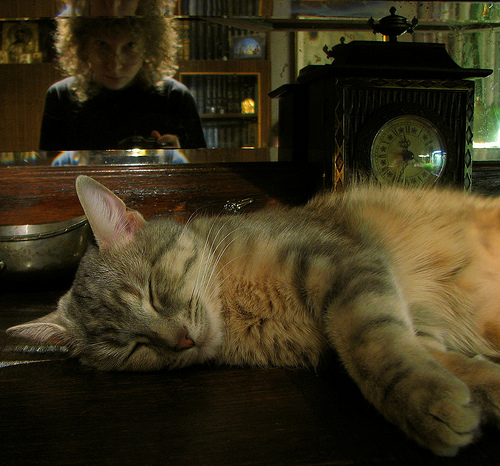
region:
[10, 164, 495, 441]
cat sleeping on the counter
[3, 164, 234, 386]
head of a sleeping cat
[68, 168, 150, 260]
fuzzy pink ear of cat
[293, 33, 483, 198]
wood encased clock with roman numerals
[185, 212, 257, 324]
white whiskers on a cat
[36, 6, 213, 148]
curly haired lady with glasses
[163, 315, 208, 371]
triangular pink nose of cat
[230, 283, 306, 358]
brown bib on a cat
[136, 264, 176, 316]
slitted eye of a cat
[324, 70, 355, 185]
decorative trim around a clock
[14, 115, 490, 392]
a cat laying on table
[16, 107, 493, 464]
a cat inside the house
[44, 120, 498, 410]
a cat laying inside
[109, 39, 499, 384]
a cat laying in front of a clock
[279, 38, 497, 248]
a clock behind the cat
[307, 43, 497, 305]
a clock behind a cat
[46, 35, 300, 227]
a women looking in the mirror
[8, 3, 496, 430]
a women and a cat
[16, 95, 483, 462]
a sleeping cat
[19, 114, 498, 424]
a sleeping cat inside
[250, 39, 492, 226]
clock on a brown box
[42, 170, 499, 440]
cat sleeping in front of mirror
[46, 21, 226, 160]
woman's reflection in mirror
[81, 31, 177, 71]
woman wearing eye glasses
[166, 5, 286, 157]
large brown book shelf in background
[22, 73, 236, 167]
woman wearing black shirt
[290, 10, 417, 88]
poster on wall in reflection in mirror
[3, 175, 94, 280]
silver bowl under brown shelf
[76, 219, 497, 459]
grey and brown cat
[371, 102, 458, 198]
white clock face with black numbers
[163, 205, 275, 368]
LONG WHITE CAT WHISKERS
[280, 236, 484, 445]
STRIPED CAT PAWS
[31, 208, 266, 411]
CAT'S FACE WHILE SLEEPING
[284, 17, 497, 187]
CLOCK SITTING IN BACKGROUND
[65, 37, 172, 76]
WOMAN WITH GLASSES ON HER NOSE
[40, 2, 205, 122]
WOMAN WITH VERY CURLY HAIR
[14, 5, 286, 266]
WOMAN TAKING PICTURE OF A CAT LAYING NEXT TO A MIRROR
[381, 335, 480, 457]
A CAT PAW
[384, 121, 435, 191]
CLOCK ARMS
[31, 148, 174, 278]
A CAT EAR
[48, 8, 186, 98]
a woman with wild curly hair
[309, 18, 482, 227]
a clock on a shelf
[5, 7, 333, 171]
a mirror on a dresser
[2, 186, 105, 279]
a silver bowl on a dresser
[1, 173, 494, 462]
a brown wooden dresser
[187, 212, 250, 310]
white whiskers on a cat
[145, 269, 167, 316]
a closed cat eye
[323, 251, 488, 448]
the front leg of a cat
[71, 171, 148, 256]
an ear of a cat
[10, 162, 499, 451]
a cat lying on a dresser